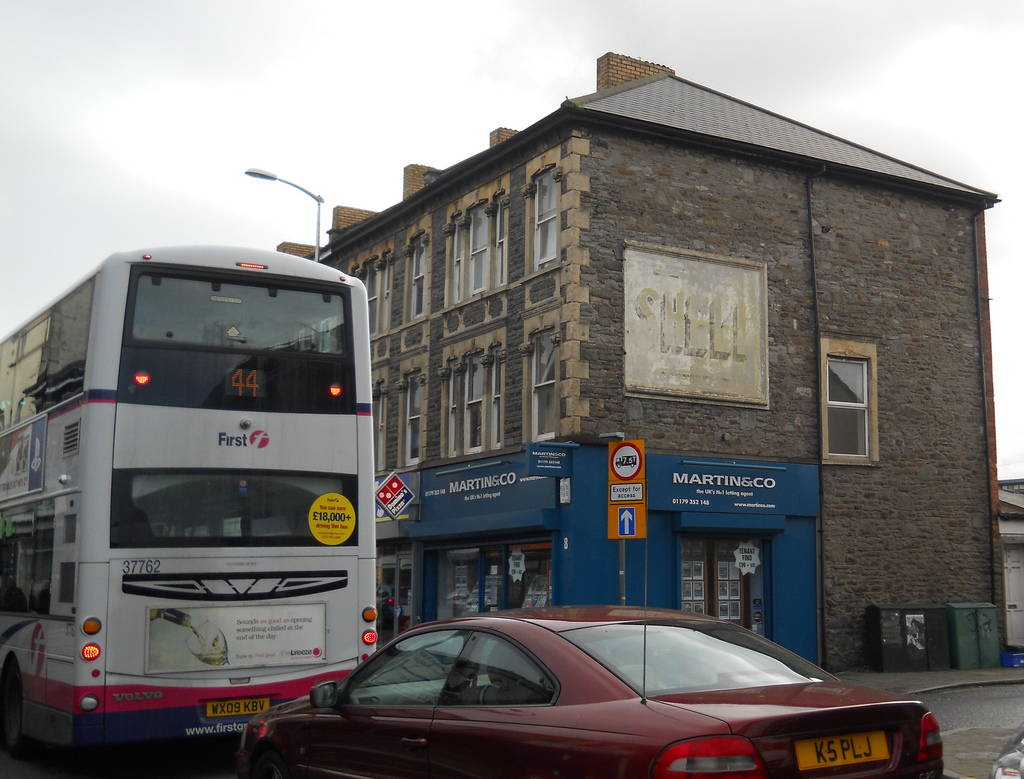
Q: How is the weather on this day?
A: It is cloudy.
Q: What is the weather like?
A: It is cloudy.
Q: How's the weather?
A: It is cloudy.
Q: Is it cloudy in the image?
A: Yes, it is cloudy.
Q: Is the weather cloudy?
A: Yes, it is cloudy.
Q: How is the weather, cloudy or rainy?
A: It is cloudy.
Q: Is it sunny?
A: No, it is cloudy.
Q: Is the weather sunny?
A: No, it is cloudy.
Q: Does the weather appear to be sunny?
A: No, it is cloudy.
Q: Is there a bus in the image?
A: Yes, there is a bus.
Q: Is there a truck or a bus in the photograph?
A: Yes, there is a bus.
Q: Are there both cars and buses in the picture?
A: Yes, there are both a bus and a car.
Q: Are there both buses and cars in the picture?
A: Yes, there are both a bus and a car.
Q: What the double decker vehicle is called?
A: The vehicle is a bus.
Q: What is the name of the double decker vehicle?
A: The vehicle is a bus.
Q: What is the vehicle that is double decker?
A: The vehicle is a bus.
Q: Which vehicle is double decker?
A: The vehicle is a bus.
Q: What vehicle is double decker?
A: The vehicle is a bus.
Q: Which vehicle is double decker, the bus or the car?
A: The bus is double decker.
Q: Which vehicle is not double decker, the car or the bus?
A: The car is not double decker.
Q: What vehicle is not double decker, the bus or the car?
A: The car is not double decker.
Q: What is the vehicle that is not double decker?
A: The vehicle is a car.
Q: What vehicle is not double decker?
A: The vehicle is a car.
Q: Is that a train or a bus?
A: That is a bus.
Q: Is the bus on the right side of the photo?
A: No, the bus is on the left of the image.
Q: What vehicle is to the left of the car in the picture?
A: The vehicle is a bus.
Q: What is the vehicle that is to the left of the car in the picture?
A: The vehicle is a bus.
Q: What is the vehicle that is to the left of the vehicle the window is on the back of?
A: The vehicle is a bus.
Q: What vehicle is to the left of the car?
A: The vehicle is a bus.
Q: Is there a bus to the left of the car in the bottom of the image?
A: Yes, there is a bus to the left of the car.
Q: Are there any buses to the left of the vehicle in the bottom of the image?
A: Yes, there is a bus to the left of the car.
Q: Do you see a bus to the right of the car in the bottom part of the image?
A: No, the bus is to the left of the car.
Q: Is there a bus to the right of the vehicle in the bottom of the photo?
A: No, the bus is to the left of the car.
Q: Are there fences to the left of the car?
A: No, there is a bus to the left of the car.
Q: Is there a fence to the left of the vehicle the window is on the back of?
A: No, there is a bus to the left of the car.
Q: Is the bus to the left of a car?
A: Yes, the bus is to the left of a car.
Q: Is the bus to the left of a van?
A: No, the bus is to the left of a car.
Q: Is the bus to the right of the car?
A: No, the bus is to the left of the car.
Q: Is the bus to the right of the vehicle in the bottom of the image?
A: No, the bus is to the left of the car.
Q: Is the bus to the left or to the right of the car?
A: The bus is to the left of the car.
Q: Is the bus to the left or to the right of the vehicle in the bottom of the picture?
A: The bus is to the left of the car.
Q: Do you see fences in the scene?
A: No, there are no fences.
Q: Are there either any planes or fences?
A: No, there are no fences or planes.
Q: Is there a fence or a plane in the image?
A: No, there are no fences or airplanes.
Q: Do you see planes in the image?
A: No, there are no planes.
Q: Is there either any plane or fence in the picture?
A: No, there are no airplanes or fences.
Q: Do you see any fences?
A: No, there are no fences.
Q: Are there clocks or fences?
A: No, there are no fences or clocks.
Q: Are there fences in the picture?
A: No, there are no fences.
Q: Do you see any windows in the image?
A: Yes, there is a window.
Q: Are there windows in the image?
A: Yes, there is a window.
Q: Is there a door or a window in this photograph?
A: Yes, there is a window.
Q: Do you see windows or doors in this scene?
A: Yes, there is a window.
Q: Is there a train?
A: No, there are no trains.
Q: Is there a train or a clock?
A: No, there are no trains or clocks.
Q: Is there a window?
A: Yes, there is a window.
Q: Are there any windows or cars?
A: Yes, there is a window.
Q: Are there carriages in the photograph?
A: No, there are no carriages.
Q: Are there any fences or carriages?
A: No, there are no carriages or fences.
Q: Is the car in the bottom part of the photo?
A: Yes, the car is in the bottom of the image.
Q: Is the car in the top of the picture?
A: No, the car is in the bottom of the image.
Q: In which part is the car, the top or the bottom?
A: The car is in the bottom of the image.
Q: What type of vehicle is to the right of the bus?
A: The vehicle is a car.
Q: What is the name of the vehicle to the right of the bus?
A: The vehicle is a car.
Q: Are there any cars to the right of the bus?
A: Yes, there is a car to the right of the bus.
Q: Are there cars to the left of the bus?
A: No, the car is to the right of the bus.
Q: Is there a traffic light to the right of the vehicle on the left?
A: No, there is a car to the right of the bus.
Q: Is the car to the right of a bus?
A: Yes, the car is to the right of a bus.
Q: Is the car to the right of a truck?
A: No, the car is to the right of a bus.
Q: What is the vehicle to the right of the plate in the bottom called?
A: The vehicle is a car.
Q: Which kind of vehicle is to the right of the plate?
A: The vehicle is a car.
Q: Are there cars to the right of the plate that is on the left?
A: Yes, there is a car to the right of the plate.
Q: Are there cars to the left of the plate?
A: No, the car is to the right of the plate.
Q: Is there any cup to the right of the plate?
A: No, there is a car to the right of the plate.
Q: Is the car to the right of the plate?
A: Yes, the car is to the right of the plate.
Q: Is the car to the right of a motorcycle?
A: No, the car is to the right of the plate.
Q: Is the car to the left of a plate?
A: No, the car is to the right of a plate.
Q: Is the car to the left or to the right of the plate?
A: The car is to the right of the plate.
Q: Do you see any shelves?
A: No, there are no shelves.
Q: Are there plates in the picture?
A: Yes, there is a plate.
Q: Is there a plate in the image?
A: Yes, there is a plate.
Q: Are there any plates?
A: Yes, there is a plate.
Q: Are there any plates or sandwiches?
A: Yes, there is a plate.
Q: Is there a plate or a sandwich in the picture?
A: Yes, there is a plate.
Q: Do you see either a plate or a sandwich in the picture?
A: Yes, there is a plate.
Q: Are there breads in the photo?
A: No, there are no breads.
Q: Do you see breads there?
A: No, there are no breads.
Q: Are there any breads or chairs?
A: No, there are no breads or chairs.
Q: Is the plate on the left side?
A: Yes, the plate is on the left of the image.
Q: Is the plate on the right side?
A: No, the plate is on the left of the image.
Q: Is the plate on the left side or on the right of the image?
A: The plate is on the left of the image.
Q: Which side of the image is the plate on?
A: The plate is on the left of the image.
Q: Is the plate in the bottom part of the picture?
A: Yes, the plate is in the bottom of the image.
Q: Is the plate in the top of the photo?
A: No, the plate is in the bottom of the image.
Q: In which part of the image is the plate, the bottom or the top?
A: The plate is in the bottom of the image.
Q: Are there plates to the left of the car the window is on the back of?
A: Yes, there is a plate to the left of the car.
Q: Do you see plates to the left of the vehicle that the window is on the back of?
A: Yes, there is a plate to the left of the car.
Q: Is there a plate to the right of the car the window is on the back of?
A: No, the plate is to the left of the car.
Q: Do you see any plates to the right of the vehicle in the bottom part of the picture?
A: No, the plate is to the left of the car.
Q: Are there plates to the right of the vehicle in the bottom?
A: No, the plate is to the left of the car.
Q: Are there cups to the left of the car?
A: No, there is a plate to the left of the car.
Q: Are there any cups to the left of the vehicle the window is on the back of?
A: No, there is a plate to the left of the car.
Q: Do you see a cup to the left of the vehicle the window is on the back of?
A: No, there is a plate to the left of the car.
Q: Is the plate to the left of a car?
A: Yes, the plate is to the left of a car.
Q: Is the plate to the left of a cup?
A: No, the plate is to the left of a car.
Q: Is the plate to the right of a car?
A: No, the plate is to the left of a car.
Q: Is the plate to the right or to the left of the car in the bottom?
A: The plate is to the left of the car.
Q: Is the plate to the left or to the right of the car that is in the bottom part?
A: The plate is to the left of the car.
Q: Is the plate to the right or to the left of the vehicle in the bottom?
A: The plate is to the left of the car.